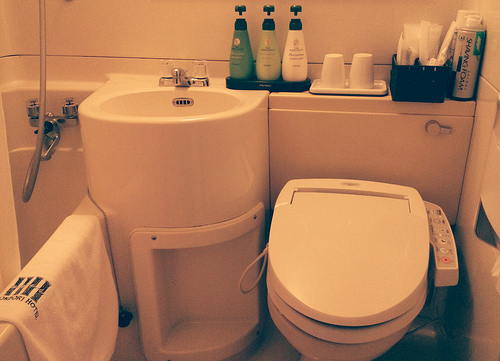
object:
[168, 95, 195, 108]
drain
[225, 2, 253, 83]
bottle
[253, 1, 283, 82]
bottle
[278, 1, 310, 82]
bottle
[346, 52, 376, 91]
cups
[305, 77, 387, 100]
tray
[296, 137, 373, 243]
side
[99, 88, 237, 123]
sink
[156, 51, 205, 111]
shower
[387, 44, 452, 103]
box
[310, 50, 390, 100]
two stacks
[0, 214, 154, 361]
towel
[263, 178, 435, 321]
lid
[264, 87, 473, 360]
toilet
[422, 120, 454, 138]
knob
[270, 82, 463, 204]
tank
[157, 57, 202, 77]
knobs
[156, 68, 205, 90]
faucet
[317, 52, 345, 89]
cups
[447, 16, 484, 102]
can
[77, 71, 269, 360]
bathroom sink